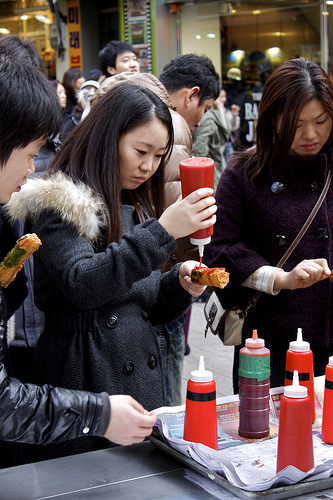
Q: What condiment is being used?
A: Ketchup.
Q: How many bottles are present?
A: Six.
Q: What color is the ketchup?
A: Red.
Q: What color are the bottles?
A: Red.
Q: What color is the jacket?
A: Black.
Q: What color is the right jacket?
A: Purple.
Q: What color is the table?
A: Black.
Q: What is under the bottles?
A: Newspapers.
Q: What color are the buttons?
A: Black.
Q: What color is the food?
A: Brown.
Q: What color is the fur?
A: Tan.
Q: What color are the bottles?
A: Red.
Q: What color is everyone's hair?
A: Black.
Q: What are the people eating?
A: Corn dogs.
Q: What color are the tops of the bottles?
A: White.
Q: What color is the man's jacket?
A: Black.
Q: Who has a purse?
A: A woman in a purple coat.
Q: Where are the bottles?
A: On top of newspaper.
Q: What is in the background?
A: Storefronts.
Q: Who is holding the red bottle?
A: A woman.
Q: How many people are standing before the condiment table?
A: 3.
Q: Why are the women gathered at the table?
A: To put condiments on the corn dogs.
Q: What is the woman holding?
A: Squeeze bottle.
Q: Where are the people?
A: The city.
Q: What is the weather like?
A: Cold.